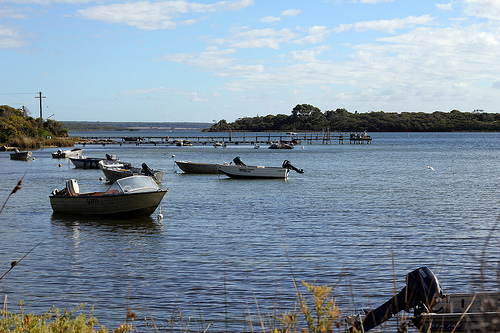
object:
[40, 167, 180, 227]
boat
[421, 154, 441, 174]
bird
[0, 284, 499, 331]
shore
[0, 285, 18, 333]
plants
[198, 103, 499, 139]
peninsula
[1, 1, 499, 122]
sky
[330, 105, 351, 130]
trees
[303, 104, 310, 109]
leaves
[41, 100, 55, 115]
power lines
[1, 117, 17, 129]
shrubs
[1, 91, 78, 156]
hillside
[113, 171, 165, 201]
window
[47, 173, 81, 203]
engine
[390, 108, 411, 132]
trees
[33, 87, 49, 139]
electrical pole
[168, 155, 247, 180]
boats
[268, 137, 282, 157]
boats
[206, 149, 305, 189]
boat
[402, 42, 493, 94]
clouds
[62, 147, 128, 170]
boats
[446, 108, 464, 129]
trees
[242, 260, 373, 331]
grass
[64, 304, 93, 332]
weeds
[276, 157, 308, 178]
motor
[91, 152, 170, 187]
boats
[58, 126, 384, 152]
dock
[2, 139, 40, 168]
boat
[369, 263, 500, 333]
boat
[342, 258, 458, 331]
motor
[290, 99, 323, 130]
trees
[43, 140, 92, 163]
boats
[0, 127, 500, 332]
lake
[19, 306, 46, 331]
weeds